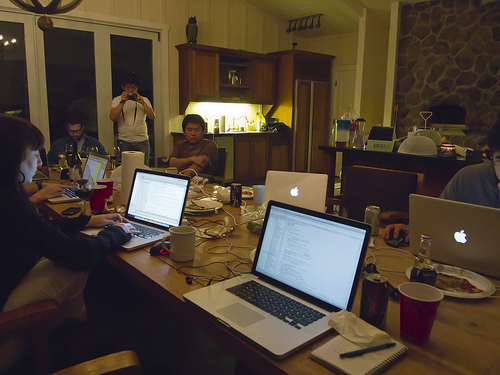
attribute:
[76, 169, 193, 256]
laptop — open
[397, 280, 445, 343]
cup — red, plastic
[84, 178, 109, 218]
cup — plastic, red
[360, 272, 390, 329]
can — soda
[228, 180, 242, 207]
can — soda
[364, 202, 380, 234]
can — soda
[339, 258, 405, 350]
soda — black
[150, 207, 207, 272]
mug — white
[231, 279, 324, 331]
keyboard — black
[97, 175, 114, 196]
cup — red, plastic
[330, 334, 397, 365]
ink pen — blue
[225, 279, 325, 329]
keyboard — black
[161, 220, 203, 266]
mug — white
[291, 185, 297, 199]
apple — white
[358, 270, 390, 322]
can — soda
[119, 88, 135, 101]
camera — black